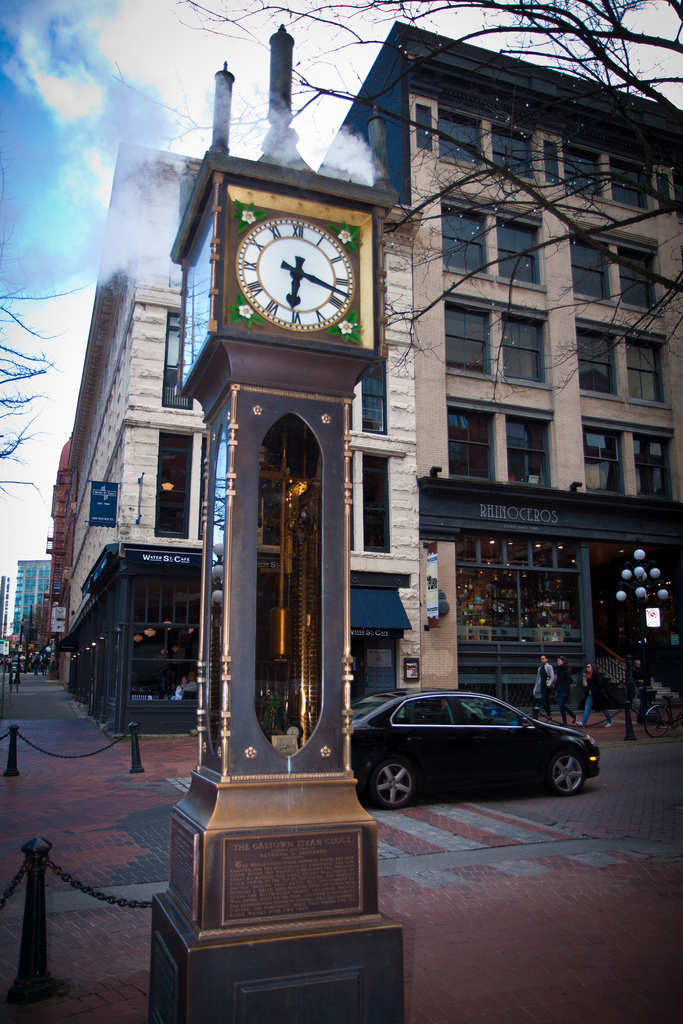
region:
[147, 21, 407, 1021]
the clock on the tower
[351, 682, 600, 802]
a black vehicle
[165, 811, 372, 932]
the plaque on the tower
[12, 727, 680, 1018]
the tiled ground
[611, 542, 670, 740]
the globe lights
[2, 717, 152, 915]
the chain links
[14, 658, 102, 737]
the long sidewalk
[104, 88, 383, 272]
the smoke in the air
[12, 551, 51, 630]
the glass and stone building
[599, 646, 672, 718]
the stair case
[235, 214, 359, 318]
A round clock face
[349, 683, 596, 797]
A black car on a street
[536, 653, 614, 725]
People walking on a sidewalk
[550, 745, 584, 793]
A front tire on a car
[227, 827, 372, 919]
A plaque on a clock tower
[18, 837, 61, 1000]
A black post on a sidewalk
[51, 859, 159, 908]
A black chain on a post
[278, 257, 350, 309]
Black hands on a clock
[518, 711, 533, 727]
A side mirror on a car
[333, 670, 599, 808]
black car parked on the street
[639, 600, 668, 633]
parking sign on the pole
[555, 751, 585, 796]
rim on the car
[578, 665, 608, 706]
woman wearing a black jacket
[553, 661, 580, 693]
woman wearing a black jacket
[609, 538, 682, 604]
lights on the black pole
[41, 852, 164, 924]
chain on the pole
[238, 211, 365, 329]
a clock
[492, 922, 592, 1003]
the ground is red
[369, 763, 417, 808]
back tire of the car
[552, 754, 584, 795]
front tire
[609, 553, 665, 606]
white lights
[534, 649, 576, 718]
two people walking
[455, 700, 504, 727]
a window on the car is clear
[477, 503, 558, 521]
silver lettered rhinoceros sign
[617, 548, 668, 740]
street lamp with multiple white globes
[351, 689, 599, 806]
black car with silver rimmed tires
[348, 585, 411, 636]
navy blue awning with white letters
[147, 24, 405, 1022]
ornate steam clock on black pedastal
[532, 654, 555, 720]
man wearing black outfit and grey jacket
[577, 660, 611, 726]
woman wearing black jacket and red scarf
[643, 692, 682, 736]
dark colored parked bicycle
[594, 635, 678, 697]
concrete steps with red railing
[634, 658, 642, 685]
man sitting on concrete stairs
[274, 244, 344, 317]
The black hands of the clock on the monument.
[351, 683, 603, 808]
The black vehicle in the street.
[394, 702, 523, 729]
The side windows of the vehicle in the street.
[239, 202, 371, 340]
The clock on the monument in the plaza.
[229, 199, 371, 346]
The flowers in each corner bordering the clock.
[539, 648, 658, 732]
The people walking on the sidewalk.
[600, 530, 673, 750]
The street lamp with white bulbs.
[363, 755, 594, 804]
The tires of the vehicle in the street.